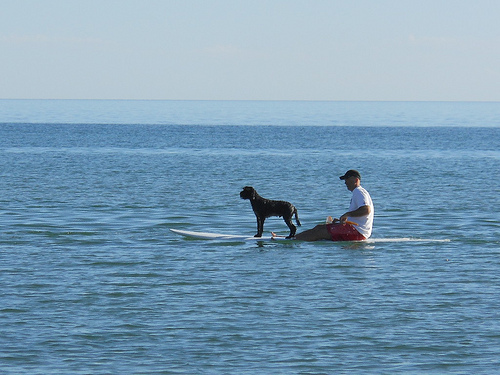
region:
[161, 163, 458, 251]
Dog and a man on a surf board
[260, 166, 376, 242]
A man is sitting on the surfboard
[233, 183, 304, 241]
The dog is standing on the surfboard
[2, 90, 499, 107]
The horizon line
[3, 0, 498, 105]
Hazy blue sky above the horizon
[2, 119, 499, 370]
Small ripples in the water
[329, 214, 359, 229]
The man has a paddle in hand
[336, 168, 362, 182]
The man is wearing a cap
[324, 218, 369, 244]
He is wearing red shorts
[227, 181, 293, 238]
black dog on surf board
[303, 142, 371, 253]
man sitting on surf board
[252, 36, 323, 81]
white clouds in blue sky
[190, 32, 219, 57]
white clouds in blue sky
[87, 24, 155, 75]
white clouds in blue sky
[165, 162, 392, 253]
man and his dog on a surfboard.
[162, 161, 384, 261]
man and his dog on a surfboard.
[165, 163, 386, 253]
man and his dog on a surfboard.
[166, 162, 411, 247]
man and his dog on a surfboard.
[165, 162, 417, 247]
man and his dog on a surfboard.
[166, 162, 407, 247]
man and his dog on a surfboard.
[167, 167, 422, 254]
man and his dog on a surfboard.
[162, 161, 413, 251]
man and his dog on a surfboard.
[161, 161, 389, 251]
man and his dog on a surfboard.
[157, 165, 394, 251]
man and his dog on a surfboard.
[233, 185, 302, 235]
the dog is standing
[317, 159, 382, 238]
the man is sitting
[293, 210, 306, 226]
the dogs tail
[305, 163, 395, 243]
man is sitting on the surfboard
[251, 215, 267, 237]
the dogs leg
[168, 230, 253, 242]
the surfboard is white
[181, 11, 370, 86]
the sky is clear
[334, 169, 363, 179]
the hat is black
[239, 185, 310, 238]
the dog is black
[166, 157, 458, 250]
Man and dog on a surfboard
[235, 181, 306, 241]
The dog is black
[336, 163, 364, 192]
Hat on man's head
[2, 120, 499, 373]
The water appears to be calm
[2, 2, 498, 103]
The sky is clear and blue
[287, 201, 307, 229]
Black tail of a dog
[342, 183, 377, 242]
The shirt is white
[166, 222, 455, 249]
The surfboard is long and white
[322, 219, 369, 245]
A pair of red shorts